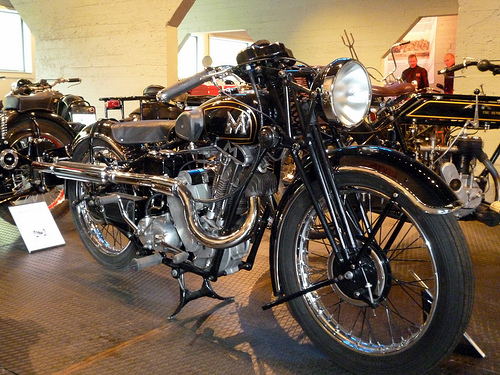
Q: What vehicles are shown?
A: Motorcycles.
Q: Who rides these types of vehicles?
A: Bikers.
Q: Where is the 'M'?
A: On nearest motorcycle.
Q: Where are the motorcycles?
A: On black mat.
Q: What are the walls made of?
A: Cinderblocks.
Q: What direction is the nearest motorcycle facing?
A: Right.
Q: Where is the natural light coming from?
A: Windows.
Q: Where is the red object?
A: Behind the motorcycles.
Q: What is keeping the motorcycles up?
A: Kickstands.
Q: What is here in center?
A: Motorcycle.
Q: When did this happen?
A: During the day time.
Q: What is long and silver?
A: Exhaust pipe.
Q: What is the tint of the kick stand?
A: Black metal.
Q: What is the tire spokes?
A: Silver metal cycle.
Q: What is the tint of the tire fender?
A: Black and silver.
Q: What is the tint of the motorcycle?
A: Black and chrome.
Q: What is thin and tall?
A: Black tire.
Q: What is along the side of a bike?
A: Chrome bar.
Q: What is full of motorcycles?
A: The room.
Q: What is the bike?
A: A motorcycle.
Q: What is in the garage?
A: Bikes.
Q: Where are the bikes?
A: In a garage.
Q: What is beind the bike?
A: A motorcycle.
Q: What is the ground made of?
A: Tile.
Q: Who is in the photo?
A: Noone.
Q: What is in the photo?
A: Motorcycles.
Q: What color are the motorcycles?
A: Black.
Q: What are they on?
A: Their stands.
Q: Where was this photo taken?
A: A garage.